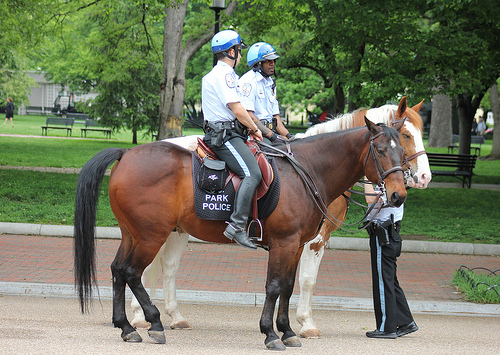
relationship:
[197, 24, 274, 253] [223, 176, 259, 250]
policeman has boots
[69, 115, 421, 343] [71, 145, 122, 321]
horse has tail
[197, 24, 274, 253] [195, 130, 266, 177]
policeman has pants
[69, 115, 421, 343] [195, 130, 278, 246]
horse has saddle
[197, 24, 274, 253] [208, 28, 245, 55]
policeman has helmet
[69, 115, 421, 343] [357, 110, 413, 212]
horse has head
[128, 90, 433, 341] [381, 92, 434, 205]
horse has head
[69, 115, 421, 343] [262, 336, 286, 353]
horse has hoof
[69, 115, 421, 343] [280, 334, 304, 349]
horse has hoof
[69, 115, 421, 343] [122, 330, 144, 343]
horse has hoof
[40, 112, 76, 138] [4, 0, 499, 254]
bench in park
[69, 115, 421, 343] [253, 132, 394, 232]
horse has harness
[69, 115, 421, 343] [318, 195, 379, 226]
horse has harness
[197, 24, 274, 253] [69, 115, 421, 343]
officer riding horse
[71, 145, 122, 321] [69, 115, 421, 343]
tail on horse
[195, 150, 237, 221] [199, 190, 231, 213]
bag states park police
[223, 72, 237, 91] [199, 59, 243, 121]
insignia on shirt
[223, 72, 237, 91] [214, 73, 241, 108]
insignia on sleeve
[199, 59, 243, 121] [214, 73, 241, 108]
shirt has sleeve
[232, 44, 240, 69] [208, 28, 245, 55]
strap holding helmet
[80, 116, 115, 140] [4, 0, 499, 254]
bench in park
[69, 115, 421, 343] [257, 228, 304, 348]
horse with leg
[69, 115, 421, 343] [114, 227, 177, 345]
horse with leg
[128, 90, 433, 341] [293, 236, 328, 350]
horse with leg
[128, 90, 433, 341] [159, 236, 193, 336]
horse with leg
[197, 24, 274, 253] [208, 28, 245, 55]
policeman wearing helmet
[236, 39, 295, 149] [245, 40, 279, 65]
policeman wearing helmet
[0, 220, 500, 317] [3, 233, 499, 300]
street made of brick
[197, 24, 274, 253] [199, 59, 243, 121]
policeman has shirt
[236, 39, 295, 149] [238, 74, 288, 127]
policeman has shirt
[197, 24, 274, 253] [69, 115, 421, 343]
policeman riding on horse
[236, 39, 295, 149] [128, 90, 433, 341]
policeman riding on horse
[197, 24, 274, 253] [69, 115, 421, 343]
policeman on horse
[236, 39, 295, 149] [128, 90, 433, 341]
policeman on horse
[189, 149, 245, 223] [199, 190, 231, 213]
sign says park police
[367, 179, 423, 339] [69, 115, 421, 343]
officer hidden by horse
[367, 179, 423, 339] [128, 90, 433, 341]
officer hidden by horse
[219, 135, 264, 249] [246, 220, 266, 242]
leg out of stirrup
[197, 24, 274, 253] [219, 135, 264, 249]
officer has leg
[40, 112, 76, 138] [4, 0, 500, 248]
bench in background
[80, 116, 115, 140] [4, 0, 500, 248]
bench in background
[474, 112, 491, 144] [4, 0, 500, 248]
person in background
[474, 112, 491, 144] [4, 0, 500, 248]
person walking in background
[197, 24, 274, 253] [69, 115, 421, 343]
policeman sitting on horse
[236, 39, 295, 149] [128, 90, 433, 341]
policeman sitting on horse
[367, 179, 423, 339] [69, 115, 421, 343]
officer next to horse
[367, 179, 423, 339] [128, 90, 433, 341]
officer next to horse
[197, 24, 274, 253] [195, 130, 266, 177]
policeman wearing pants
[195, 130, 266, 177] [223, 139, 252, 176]
pants with stripe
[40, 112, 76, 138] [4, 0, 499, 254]
bench sitting in park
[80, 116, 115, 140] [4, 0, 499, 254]
bench sitting in park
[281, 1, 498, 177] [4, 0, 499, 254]
tree in park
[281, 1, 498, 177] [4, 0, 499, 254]
tree growing in park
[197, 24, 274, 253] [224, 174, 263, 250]
policeman wearing boots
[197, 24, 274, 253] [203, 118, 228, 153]
policeman wearing firearm